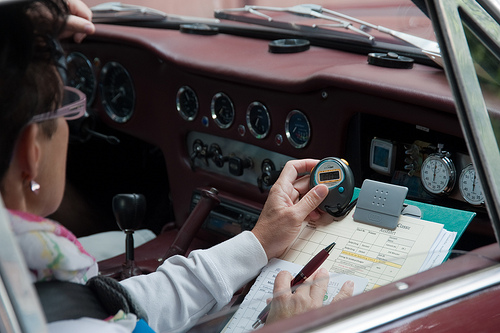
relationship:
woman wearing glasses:
[1, 13, 354, 331] [29, 84, 88, 121]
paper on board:
[390, 236, 426, 273] [439, 205, 478, 237]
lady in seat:
[3, 11, 341, 326] [0, 187, 138, 331]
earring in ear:
[21, 174, 44, 205] [25, 124, 45, 193]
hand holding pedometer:
[254, 156, 336, 263] [307, 151, 353, 219]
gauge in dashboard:
[247, 104, 272, 138] [117, 22, 467, 169]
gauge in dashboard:
[282, 107, 310, 145] [117, 22, 467, 169]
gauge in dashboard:
[209, 89, 240, 131] [117, 22, 467, 169]